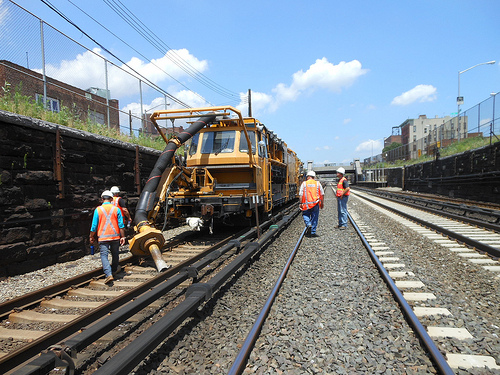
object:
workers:
[334, 166, 354, 229]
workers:
[298, 168, 326, 240]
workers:
[105, 185, 136, 248]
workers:
[88, 189, 126, 284]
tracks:
[1, 280, 100, 374]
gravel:
[327, 364, 339, 371]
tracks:
[359, 249, 499, 276]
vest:
[334, 176, 349, 200]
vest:
[300, 179, 324, 211]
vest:
[111, 195, 128, 224]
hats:
[337, 166, 346, 175]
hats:
[306, 170, 316, 178]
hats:
[111, 185, 120, 193]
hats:
[101, 190, 114, 200]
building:
[1, 58, 127, 136]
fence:
[1, 0, 144, 125]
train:
[160, 104, 312, 234]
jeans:
[335, 196, 350, 228]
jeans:
[301, 205, 321, 234]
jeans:
[97, 240, 122, 276]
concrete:
[444, 355, 495, 367]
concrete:
[425, 327, 475, 339]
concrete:
[413, 306, 452, 315]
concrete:
[401, 292, 439, 302]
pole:
[456, 71, 462, 136]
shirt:
[89, 204, 124, 242]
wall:
[1, 110, 48, 249]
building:
[398, 113, 469, 160]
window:
[51, 99, 61, 112]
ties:
[7, 304, 30, 321]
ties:
[38, 292, 56, 306]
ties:
[67, 284, 81, 296]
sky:
[1, 1, 497, 74]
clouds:
[392, 82, 438, 107]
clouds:
[296, 57, 368, 91]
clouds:
[155, 48, 206, 77]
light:
[485, 61, 495, 65]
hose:
[134, 115, 210, 222]